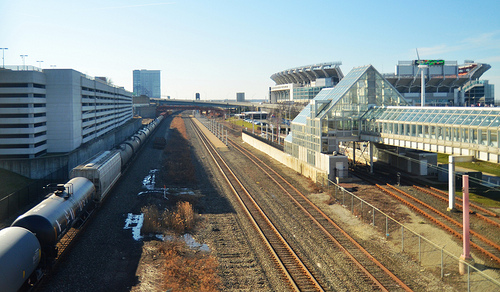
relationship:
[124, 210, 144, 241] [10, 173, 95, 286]
puddle next to train cart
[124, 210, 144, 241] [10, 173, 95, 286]
puddle behind train cart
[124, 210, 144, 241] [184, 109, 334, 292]
puddle behind track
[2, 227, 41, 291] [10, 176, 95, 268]
tanker car in front of train cart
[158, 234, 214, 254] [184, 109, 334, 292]
water next to track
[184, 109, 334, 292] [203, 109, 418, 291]
track next to track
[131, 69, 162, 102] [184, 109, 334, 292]
buildling behind track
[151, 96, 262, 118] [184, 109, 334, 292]
bridge over track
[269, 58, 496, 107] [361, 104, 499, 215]
stadium behind monorail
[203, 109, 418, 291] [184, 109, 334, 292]
track next to track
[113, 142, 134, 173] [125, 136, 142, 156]
train car in front of train car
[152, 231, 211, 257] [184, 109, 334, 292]
puddle behind track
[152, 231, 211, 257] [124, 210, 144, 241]
puddle next to puddle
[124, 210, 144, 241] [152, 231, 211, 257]
puddle next to puddle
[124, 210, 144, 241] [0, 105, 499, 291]
puddle on ground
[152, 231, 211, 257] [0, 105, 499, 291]
puddle on ground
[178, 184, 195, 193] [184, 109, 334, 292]
puddle behind track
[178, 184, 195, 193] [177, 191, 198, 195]
puddle next to puddle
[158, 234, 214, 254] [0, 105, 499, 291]
water on ground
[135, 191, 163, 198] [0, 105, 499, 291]
water on ground